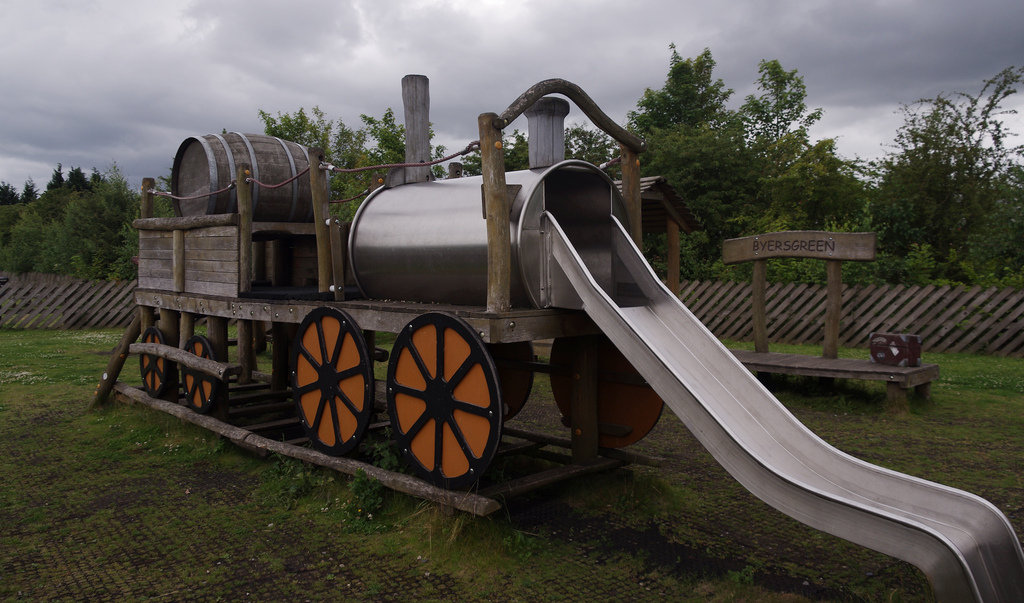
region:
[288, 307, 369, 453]
playground has a wheel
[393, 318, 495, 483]
playground has a wheel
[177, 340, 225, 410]
playground has a wheel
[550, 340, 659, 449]
playground has a wheel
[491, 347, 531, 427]
playground has a wheel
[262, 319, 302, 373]
playground has a wheel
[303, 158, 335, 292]
playground has a post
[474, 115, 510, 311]
playground has a post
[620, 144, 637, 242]
playground has a post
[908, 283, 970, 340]
wooden slat on leaning fence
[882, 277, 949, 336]
wooden slat on leaning fence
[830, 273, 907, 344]
wooden slat on leaning fence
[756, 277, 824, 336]
wooden slat on leaning fence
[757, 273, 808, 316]
wooden slat on leaning fence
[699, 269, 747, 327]
wooden slat on leaning fence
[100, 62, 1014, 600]
A playground toy shaped like a train with a slide on it.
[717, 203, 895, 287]
A wooden sign that says Byersgreen.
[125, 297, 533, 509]
Train wheels that are orange.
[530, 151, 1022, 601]
A steel slide that curves some.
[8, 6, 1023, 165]
A sky with rain clouds.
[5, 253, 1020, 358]
A wooden fence with slats that slant.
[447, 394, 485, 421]
black line on tire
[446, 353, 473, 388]
black line on tire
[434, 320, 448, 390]
black line on tire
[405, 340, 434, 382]
black line on tire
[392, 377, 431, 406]
black line on tire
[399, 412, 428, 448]
black line on tire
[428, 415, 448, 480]
black line on tire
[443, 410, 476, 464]
black line on tire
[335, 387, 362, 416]
black line on tire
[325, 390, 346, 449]
black line on tire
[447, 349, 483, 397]
black line on tire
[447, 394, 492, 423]
black line on tire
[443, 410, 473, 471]
black line on tire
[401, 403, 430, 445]
black line on tire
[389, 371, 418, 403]
black line on tire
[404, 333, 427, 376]
black line on tire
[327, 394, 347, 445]
black line on tire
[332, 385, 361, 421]
black line on tire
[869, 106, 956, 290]
A tree in the woods.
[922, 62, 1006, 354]
A tree in the woods.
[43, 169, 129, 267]
A tree in the woods.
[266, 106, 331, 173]
A tree in the woods.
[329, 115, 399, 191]
A tree in the woods.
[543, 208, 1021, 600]
chrome slide in park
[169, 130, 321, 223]
decorative barrell on slide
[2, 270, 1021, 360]
wooden fence behind slide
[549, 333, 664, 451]
decorative wheel on slide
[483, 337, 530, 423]
decorative wheel on slide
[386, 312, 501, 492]
decorative wheel on slide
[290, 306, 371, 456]
decorative wheel on slide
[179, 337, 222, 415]
decorative wheel on slide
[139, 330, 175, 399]
decorative wheel on slide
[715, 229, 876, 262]
sign next to slide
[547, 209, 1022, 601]
the slide is silver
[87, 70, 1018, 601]
the jungle gym is shaped like a train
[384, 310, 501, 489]
the wheel is black and orange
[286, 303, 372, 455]
the wheel is black and orange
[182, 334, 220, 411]
the wheel is black and orange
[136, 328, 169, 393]
the wheel is black and orange